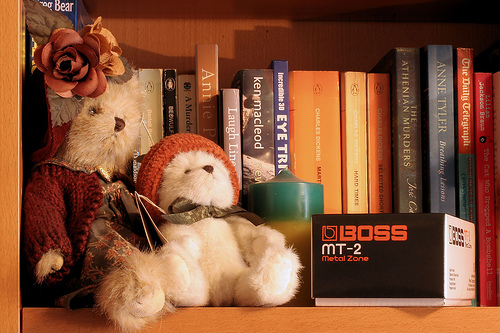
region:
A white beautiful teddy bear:
[126, 152, 306, 308]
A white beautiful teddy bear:
[50, 43, 160, 308]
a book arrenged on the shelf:
[470, 68, 497, 263]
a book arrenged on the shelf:
[451, 42, 476, 214]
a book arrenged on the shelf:
[425, 43, 457, 192]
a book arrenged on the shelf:
[388, 38, 428, 191]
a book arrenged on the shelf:
[361, 64, 404, 201]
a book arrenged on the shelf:
[290, 68, 345, 181]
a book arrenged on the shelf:
[231, 53, 293, 183]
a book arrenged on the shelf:
[187, 38, 222, 135]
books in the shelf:
[102, 22, 499, 327]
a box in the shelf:
[298, 194, 498, 328]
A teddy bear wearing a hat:
[126, 129, 296, 303]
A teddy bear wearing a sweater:
[31, 30, 159, 307]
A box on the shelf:
[311, 202, 481, 312]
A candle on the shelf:
[249, 165, 336, 290]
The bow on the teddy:
[168, 191, 253, 228]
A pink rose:
[36, 29, 104, 100]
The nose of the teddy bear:
[202, 160, 214, 172]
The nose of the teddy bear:
[108, 115, 124, 130]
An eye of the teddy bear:
[86, 105, 98, 116]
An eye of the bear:
[182, 167, 192, 174]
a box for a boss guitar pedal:
[310, 211, 476, 308]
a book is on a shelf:
[237, 68, 275, 185]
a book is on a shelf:
[269, 57, 289, 177]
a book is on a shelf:
[289, 69, 341, 215]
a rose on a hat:
[35, 27, 106, 99]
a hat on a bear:
[140, 130, 242, 212]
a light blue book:
[424, 43, 457, 215]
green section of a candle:
[245, 163, 325, 218]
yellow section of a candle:
[261, 221, 311, 306]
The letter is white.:
[198, 63, 218, 83]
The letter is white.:
[274, 108, 288, 123]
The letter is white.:
[275, 119, 289, 133]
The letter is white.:
[273, 130, 288, 144]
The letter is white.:
[273, 140, 290, 155]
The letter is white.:
[272, 150, 291, 165]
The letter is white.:
[321, 240, 338, 256]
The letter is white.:
[333, 238, 349, 255]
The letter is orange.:
[373, 219, 390, 246]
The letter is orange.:
[388, 218, 410, 247]